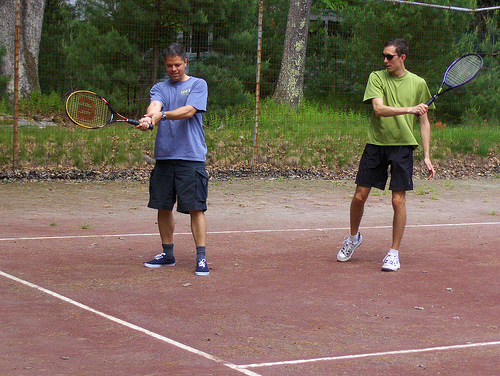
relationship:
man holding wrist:
[139, 44, 212, 276] [144, 112, 158, 123]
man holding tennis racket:
[139, 44, 212, 276] [64, 90, 154, 131]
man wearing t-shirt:
[334, 38, 437, 272] [362, 68, 437, 147]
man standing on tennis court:
[139, 44, 212, 276] [1, 218, 498, 375]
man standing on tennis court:
[334, 38, 437, 272] [1, 218, 498, 375]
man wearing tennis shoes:
[139, 44, 212, 276] [143, 254, 211, 277]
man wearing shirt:
[139, 44, 212, 276] [149, 77, 208, 160]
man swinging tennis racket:
[139, 44, 212, 276] [64, 90, 154, 131]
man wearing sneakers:
[334, 38, 437, 272] [333, 232, 402, 272]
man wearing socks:
[139, 44, 212, 276] [159, 241, 207, 257]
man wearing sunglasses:
[334, 38, 437, 272] [380, 53, 403, 59]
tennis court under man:
[1, 218, 498, 375] [139, 44, 212, 276]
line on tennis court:
[241, 334, 500, 369] [1, 218, 498, 375]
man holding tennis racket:
[334, 38, 437, 272] [427, 52, 484, 103]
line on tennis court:
[0, 268, 234, 375] [1, 218, 498, 375]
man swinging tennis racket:
[334, 38, 437, 272] [427, 52, 484, 103]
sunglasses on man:
[380, 53, 403, 59] [334, 38, 437, 272]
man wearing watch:
[139, 44, 212, 276] [160, 110, 168, 122]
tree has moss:
[270, 0, 310, 110] [288, 67, 301, 103]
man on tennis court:
[139, 44, 212, 276] [1, 218, 498, 375]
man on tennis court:
[334, 38, 437, 272] [1, 218, 498, 375]